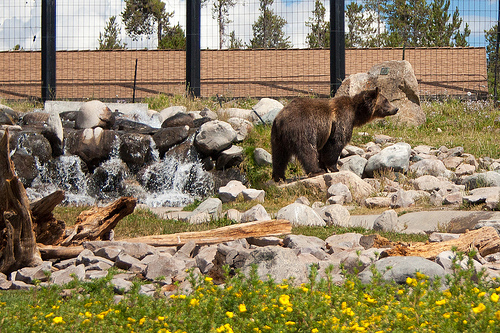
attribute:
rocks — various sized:
[2, 61, 493, 293]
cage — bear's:
[1, 1, 498, 332]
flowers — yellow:
[44, 293, 494, 332]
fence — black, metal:
[0, 6, 498, 103]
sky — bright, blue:
[4, 3, 494, 48]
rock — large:
[349, 256, 451, 291]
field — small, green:
[2, 70, 484, 332]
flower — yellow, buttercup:
[73, 272, 467, 331]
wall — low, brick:
[4, 50, 493, 105]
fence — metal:
[2, 2, 492, 97]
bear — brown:
[264, 85, 401, 185]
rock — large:
[458, 170, 498, 191]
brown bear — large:
[262, 83, 397, 182]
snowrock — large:
[367, 133, 414, 202]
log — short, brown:
[359, 214, 497, 273]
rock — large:
[33, 122, 232, 209]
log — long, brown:
[29, 194, 281, 266]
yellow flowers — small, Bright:
[41, 273, 493, 331]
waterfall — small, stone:
[36, 134, 238, 201]